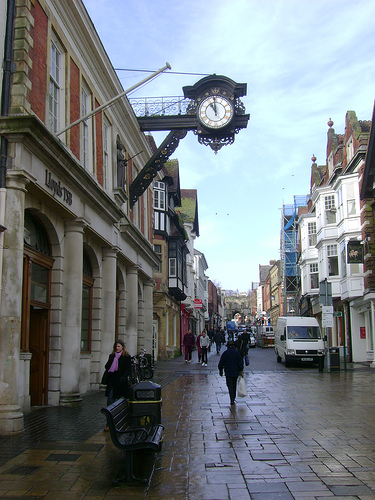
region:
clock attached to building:
[128, 63, 246, 212]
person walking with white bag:
[222, 342, 252, 403]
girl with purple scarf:
[107, 335, 125, 391]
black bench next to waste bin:
[100, 380, 163, 478]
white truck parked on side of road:
[280, 314, 325, 368]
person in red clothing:
[182, 327, 194, 367]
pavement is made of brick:
[165, 413, 371, 499]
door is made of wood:
[30, 303, 48, 403]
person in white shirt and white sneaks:
[201, 331, 212, 371]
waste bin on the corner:
[327, 342, 346, 380]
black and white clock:
[192, 94, 237, 130]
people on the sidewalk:
[165, 298, 273, 407]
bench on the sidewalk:
[100, 391, 165, 489]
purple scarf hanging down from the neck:
[106, 349, 127, 373]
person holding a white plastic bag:
[215, 337, 254, 407]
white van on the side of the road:
[265, 313, 332, 373]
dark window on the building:
[320, 193, 337, 210]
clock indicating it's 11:
[194, 93, 238, 129]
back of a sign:
[316, 278, 337, 304]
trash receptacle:
[125, 380, 168, 427]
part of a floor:
[252, 453, 274, 472]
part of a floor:
[243, 460, 266, 497]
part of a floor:
[232, 451, 249, 474]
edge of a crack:
[226, 449, 252, 483]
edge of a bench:
[139, 435, 157, 446]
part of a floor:
[204, 430, 235, 476]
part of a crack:
[215, 449, 256, 483]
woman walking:
[97, 336, 138, 434]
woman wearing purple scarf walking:
[100, 337, 135, 435]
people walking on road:
[97, 314, 253, 436]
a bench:
[97, 395, 168, 491]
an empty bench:
[98, 392, 170, 490]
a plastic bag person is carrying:
[235, 376, 249, 398]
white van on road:
[272, 313, 328, 371]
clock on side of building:
[194, 90, 236, 133]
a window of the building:
[326, 242, 339, 277]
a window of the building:
[151, 178, 166, 209]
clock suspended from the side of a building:
[139, 69, 254, 165]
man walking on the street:
[216, 337, 256, 410]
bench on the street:
[104, 397, 168, 465]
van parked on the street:
[271, 304, 320, 369]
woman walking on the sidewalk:
[100, 333, 130, 399]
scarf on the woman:
[106, 346, 124, 379]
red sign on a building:
[190, 293, 203, 314]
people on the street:
[176, 321, 209, 366]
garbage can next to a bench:
[129, 381, 165, 415]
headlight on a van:
[284, 343, 299, 363]